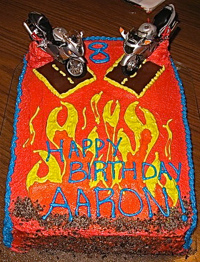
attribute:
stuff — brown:
[12, 203, 190, 256]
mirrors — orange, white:
[116, 25, 151, 49]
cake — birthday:
[18, 23, 176, 171]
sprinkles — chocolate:
[55, 218, 146, 230]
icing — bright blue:
[179, 82, 197, 183]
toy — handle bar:
[54, 24, 90, 79]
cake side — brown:
[6, 220, 195, 260]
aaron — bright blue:
[40, 184, 170, 221]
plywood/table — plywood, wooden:
[57, 1, 126, 22]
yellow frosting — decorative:
[26, 92, 184, 207]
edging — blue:
[188, 180, 197, 227]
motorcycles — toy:
[23, 5, 181, 67]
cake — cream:
[0, 2, 193, 252]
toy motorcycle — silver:
[22, 15, 87, 78]